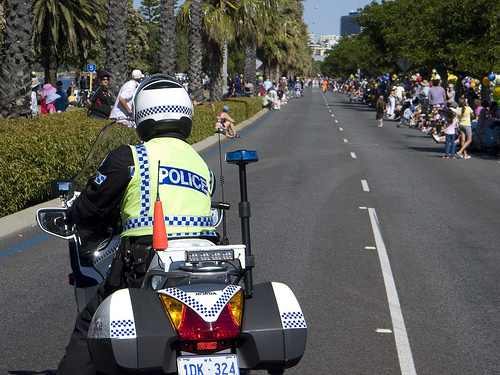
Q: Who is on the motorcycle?
A: Policeman.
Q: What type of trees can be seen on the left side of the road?
A: Palm trees.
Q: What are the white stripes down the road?
A: Road divider.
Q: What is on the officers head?
A: Helmet.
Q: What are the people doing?
A: Being spectators.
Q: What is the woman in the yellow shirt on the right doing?
A: Standing by a little girl.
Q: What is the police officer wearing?
A: Jacket with vest.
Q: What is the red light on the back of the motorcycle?
A: Brake light.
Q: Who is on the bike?
A: Police officer.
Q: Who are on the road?
A: People at a parade.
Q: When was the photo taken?
A: Sunny day.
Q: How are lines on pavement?
A: White dotted lines.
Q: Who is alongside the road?
A: Crowds of people.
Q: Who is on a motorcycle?
A: Policeman.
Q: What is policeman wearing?
A: Yellow safety vest trimmed in blue and white checks.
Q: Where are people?
A: Lined on side of street.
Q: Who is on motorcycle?
A: Police officer.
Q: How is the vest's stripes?
A: Checkered.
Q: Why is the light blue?
A: Police light.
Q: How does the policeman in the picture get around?
A: Motorbike.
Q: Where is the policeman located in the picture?
A: Bottom center.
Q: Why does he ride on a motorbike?
A: To get around.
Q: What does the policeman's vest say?
A: Police.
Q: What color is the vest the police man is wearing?
A: Yellow black and white.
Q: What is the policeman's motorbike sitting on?
A: Road.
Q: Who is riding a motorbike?
A: Policeman.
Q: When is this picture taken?
A: Daytime.